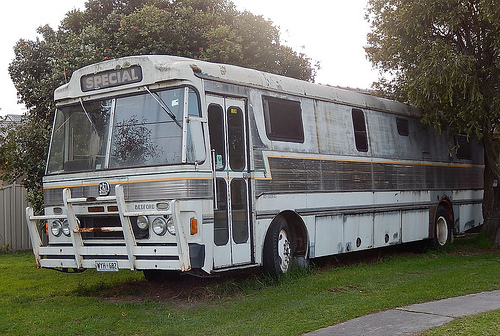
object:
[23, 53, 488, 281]
bus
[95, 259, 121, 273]
plate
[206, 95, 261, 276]
door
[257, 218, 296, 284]
tire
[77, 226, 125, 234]
bar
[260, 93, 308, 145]
windows